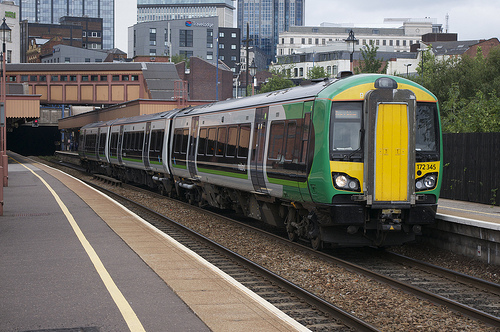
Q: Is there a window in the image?
A: Yes, there is a window.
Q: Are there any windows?
A: Yes, there is a window.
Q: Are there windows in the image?
A: Yes, there is a window.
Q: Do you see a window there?
A: Yes, there is a window.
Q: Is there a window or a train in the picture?
A: Yes, there is a window.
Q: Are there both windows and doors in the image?
A: Yes, there are both a window and a door.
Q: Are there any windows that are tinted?
A: Yes, there is a tinted window.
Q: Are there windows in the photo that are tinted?
A: Yes, there is a window that is tinted.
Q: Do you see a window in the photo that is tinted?
A: Yes, there is a window that is tinted.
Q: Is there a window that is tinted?
A: Yes, there is a window that is tinted.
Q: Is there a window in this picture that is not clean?
A: Yes, there is a tinted window.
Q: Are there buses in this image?
A: No, there are no buses.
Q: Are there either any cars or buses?
A: No, there are no buses or cars.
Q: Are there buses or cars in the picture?
A: No, there are no buses or cars.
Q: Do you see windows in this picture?
A: Yes, there is a window.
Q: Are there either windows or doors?
A: Yes, there is a window.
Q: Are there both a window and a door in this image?
A: Yes, there are both a window and a door.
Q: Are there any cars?
A: No, there are no cars.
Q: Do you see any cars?
A: No, there are no cars.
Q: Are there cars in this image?
A: No, there are no cars.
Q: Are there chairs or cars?
A: No, there are no cars or chairs.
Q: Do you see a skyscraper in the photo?
A: Yes, there is a skyscraper.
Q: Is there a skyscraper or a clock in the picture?
A: Yes, there is a skyscraper.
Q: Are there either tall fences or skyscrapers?
A: Yes, there is a tall skyscraper.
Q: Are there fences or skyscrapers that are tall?
A: Yes, the skyscraper is tall.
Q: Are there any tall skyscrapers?
A: Yes, there is a tall skyscraper.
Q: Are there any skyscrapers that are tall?
A: Yes, there is a skyscraper that is tall.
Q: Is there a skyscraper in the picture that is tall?
A: Yes, there is a skyscraper that is tall.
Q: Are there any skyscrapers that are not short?
A: Yes, there is a tall skyscraper.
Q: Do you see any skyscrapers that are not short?
A: Yes, there is a tall skyscraper.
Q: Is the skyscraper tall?
A: Yes, the skyscraper is tall.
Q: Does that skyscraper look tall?
A: Yes, the skyscraper is tall.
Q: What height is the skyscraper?
A: The skyscraper is tall.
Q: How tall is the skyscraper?
A: The skyscraper is tall.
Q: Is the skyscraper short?
A: No, the skyscraper is tall.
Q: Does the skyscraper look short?
A: No, the skyscraper is tall.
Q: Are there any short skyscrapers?
A: No, there is a skyscraper but it is tall.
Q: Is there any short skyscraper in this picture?
A: No, there is a skyscraper but it is tall.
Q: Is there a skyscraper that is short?
A: No, there is a skyscraper but it is tall.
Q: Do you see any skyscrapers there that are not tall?
A: No, there is a skyscraper but it is tall.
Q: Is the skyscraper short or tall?
A: The skyscraper is tall.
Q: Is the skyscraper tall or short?
A: The skyscraper is tall.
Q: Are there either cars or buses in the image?
A: No, there are no cars or buses.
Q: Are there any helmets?
A: No, there are no helmets.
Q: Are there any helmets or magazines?
A: No, there are no helmets or magazines.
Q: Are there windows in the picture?
A: Yes, there is a window.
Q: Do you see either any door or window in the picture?
A: Yes, there is a window.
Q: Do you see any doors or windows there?
A: Yes, there is a window.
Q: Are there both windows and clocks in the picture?
A: No, there is a window but no clocks.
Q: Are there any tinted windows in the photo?
A: Yes, there is a tinted window.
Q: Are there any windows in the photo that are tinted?
A: Yes, there is a window that is tinted.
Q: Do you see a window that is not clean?
A: Yes, there is a tinted window.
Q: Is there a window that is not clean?
A: Yes, there is a tinted window.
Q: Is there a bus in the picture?
A: No, there are no buses.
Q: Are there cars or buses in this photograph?
A: No, there are no buses or cars.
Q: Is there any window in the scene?
A: Yes, there is a window.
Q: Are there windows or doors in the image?
A: Yes, there is a window.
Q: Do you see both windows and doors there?
A: Yes, there are both a window and a door.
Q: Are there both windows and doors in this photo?
A: Yes, there are both a window and a door.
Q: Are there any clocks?
A: No, there are no clocks.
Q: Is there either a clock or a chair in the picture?
A: No, there are no clocks or chairs.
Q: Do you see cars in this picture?
A: No, there are no cars.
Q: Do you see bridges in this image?
A: Yes, there is a bridge.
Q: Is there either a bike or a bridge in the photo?
A: Yes, there is a bridge.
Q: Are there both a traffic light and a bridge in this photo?
A: No, there is a bridge but no traffic lights.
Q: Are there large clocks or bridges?
A: Yes, there is a large bridge.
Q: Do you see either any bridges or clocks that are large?
A: Yes, the bridge is large.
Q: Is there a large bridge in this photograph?
A: Yes, there is a large bridge.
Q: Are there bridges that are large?
A: Yes, there is a bridge that is large.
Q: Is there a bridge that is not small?
A: Yes, there is a large bridge.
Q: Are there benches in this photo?
A: No, there are no benches.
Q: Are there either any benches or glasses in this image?
A: No, there are no benches or glasses.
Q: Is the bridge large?
A: Yes, the bridge is large.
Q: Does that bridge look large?
A: Yes, the bridge is large.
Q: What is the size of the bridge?
A: The bridge is large.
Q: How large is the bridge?
A: The bridge is large.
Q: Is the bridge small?
A: No, the bridge is large.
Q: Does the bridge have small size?
A: No, the bridge is large.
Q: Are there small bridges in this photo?
A: No, there is a bridge but it is large.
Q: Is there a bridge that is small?
A: No, there is a bridge but it is large.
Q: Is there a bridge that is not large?
A: No, there is a bridge but it is large.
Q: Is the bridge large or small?
A: The bridge is large.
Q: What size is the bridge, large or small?
A: The bridge is large.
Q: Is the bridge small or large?
A: The bridge is large.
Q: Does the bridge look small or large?
A: The bridge is large.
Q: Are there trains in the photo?
A: Yes, there is a train.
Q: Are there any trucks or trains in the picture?
A: Yes, there is a train.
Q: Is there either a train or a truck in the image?
A: Yes, there is a train.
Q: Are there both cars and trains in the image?
A: No, there is a train but no cars.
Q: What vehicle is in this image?
A: The vehicle is a train.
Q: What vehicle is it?
A: The vehicle is a train.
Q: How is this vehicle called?
A: This is a train.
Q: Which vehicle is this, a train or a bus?
A: This is a train.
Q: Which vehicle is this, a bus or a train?
A: This is a train.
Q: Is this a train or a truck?
A: This is a train.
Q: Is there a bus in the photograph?
A: No, there are no buses.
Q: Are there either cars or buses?
A: No, there are no buses or cars.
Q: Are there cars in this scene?
A: No, there are no cars.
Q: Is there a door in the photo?
A: Yes, there is a door.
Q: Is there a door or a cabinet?
A: Yes, there is a door.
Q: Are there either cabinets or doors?
A: Yes, there is a door.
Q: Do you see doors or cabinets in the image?
A: Yes, there is a door.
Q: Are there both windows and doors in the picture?
A: Yes, there are both a door and windows.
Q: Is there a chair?
A: No, there are no chairs.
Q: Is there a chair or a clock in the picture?
A: No, there are no chairs or clocks.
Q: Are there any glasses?
A: No, there are no glasses.